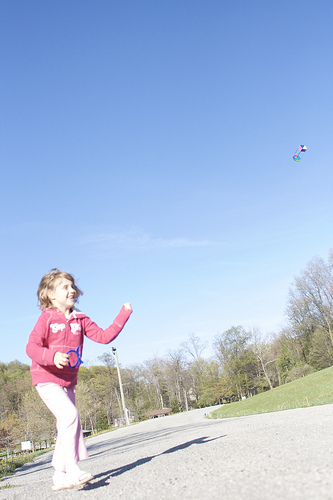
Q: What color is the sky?
A: Blue.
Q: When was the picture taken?
A: Daytime.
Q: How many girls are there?
A: One.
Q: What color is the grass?
A: Green.